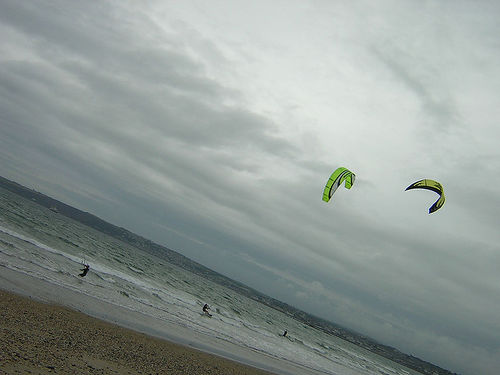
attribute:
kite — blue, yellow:
[406, 166, 448, 220]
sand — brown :
[8, 299, 72, 362]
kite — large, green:
[406, 177, 446, 212]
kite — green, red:
[321, 166, 357, 208]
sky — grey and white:
[2, 0, 499, 365]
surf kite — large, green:
[319, 160, 359, 207]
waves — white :
[131, 240, 258, 342]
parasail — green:
[324, 163, 356, 196]